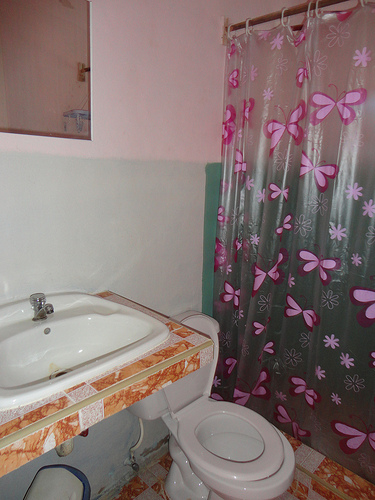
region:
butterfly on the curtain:
[310, 82, 362, 124]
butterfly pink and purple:
[290, 376, 318, 405]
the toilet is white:
[134, 310, 295, 499]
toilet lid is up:
[162, 316, 218, 411]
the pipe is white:
[54, 439, 72, 456]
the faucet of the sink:
[31, 293, 53, 319]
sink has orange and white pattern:
[0, 290, 213, 478]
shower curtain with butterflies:
[214, 3, 373, 485]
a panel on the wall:
[1, 0, 91, 139]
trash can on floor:
[23, 465, 91, 498]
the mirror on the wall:
[2, 0, 92, 143]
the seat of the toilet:
[172, 403, 290, 481]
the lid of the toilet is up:
[164, 311, 225, 407]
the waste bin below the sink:
[10, 463, 96, 498]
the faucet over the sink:
[27, 290, 56, 321]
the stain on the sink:
[45, 357, 61, 373]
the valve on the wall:
[108, 452, 149, 475]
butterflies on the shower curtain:
[224, 31, 374, 454]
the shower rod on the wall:
[225, 1, 345, 42]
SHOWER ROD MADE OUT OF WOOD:
[260, 14, 271, 19]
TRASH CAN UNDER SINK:
[49, 467, 93, 497]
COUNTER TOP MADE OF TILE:
[117, 389, 143, 404]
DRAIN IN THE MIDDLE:
[51, 365, 72, 380]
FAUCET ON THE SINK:
[31, 294, 52, 324]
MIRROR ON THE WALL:
[4, 5, 89, 129]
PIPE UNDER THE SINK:
[60, 441, 77, 457]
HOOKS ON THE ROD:
[279, 7, 285, 24]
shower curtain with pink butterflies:
[199, 0, 361, 489]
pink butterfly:
[295, 242, 344, 289]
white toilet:
[146, 305, 305, 491]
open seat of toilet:
[154, 309, 234, 418]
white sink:
[0, 283, 176, 412]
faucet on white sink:
[23, 290, 64, 328]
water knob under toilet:
[115, 446, 151, 478]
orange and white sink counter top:
[5, 286, 221, 469]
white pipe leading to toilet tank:
[122, 418, 145, 465]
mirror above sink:
[3, 1, 114, 153]